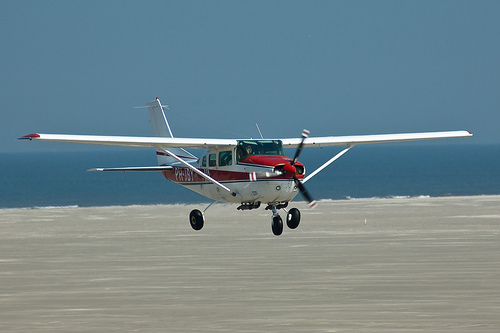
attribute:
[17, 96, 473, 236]
plane — red, white, airborne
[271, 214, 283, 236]
tire — black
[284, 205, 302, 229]
tire — black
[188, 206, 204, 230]
tire — black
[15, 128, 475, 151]
wing — wide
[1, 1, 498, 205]
sky — blue, clear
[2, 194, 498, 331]
ice — white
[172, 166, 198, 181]
writing — white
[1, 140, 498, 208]
water — calm, gray